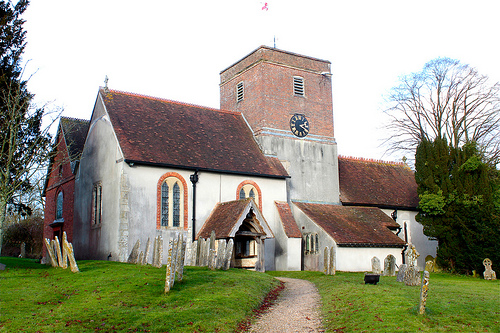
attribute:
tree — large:
[412, 139, 498, 273]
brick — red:
[278, 201, 286, 208]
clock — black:
[290, 112, 309, 137]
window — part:
[158, 183, 169, 228]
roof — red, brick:
[96, 81, 302, 188]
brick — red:
[179, 180, 186, 186]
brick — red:
[179, 194, 191, 201]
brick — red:
[180, 219, 191, 230]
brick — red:
[149, 217, 165, 228]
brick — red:
[157, 189, 164, 196]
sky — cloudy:
[415, 3, 491, 51]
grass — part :
[2, 255, 284, 331]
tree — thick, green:
[415, 132, 499, 282]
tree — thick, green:
[0, 0, 46, 203]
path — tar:
[236, 261, 336, 331]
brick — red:
[157, 103, 219, 151]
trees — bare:
[382, 57, 495, 278]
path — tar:
[237, 269, 326, 331]